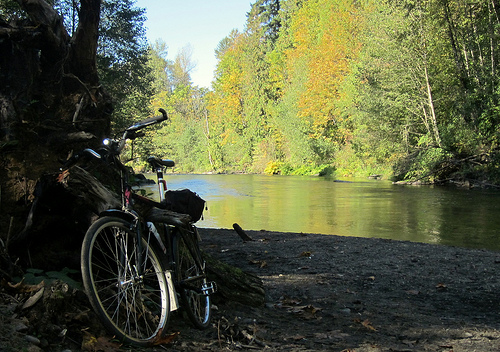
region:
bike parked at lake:
[11, 8, 476, 332]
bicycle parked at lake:
[27, 68, 345, 337]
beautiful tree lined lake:
[202, 69, 459, 246]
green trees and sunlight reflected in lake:
[219, 163, 450, 255]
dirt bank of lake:
[257, 186, 453, 306]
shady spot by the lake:
[22, 10, 392, 317]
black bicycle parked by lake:
[52, 107, 247, 331]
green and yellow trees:
[222, 10, 464, 182]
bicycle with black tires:
[66, 201, 256, 335]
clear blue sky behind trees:
[140, 2, 331, 92]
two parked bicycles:
[47, 98, 232, 343]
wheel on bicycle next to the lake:
[71, 205, 178, 350]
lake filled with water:
[135, 140, 495, 245]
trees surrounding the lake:
[132, 5, 493, 186]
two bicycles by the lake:
[30, 105, 227, 345]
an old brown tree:
[0, 1, 167, 222]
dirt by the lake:
[196, 223, 496, 348]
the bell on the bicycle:
[90, 128, 131, 158]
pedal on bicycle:
[195, 277, 222, 297]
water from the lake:
[196, 165, 498, 257]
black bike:
[54, 118, 220, 312]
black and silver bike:
[42, 108, 227, 331]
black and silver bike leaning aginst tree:
[53, 134, 231, 341]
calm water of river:
[217, 184, 267, 212]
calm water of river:
[279, 194, 331, 213]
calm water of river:
[370, 204, 423, 220]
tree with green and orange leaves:
[281, 30, 338, 93]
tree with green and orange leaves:
[224, 100, 287, 163]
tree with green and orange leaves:
[300, 67, 373, 150]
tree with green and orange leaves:
[230, 53, 263, 119]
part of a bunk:
[371, 258, 397, 299]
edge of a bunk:
[276, 220, 298, 239]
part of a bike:
[86, 278, 117, 305]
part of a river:
[312, 179, 341, 204]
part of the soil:
[284, 218, 311, 274]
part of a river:
[290, 127, 315, 199]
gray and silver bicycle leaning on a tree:
[55, 103, 220, 342]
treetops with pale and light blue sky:
[161, 0, 222, 85]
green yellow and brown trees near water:
[207, 18, 359, 184]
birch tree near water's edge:
[406, 13, 451, 155]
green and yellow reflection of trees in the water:
[205, 168, 306, 224]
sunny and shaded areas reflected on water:
[245, 171, 480, 231]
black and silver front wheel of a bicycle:
[75, 207, 174, 344]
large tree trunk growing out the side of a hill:
[57, 0, 119, 120]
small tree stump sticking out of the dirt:
[226, 220, 261, 248]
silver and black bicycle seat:
[140, 147, 177, 207]